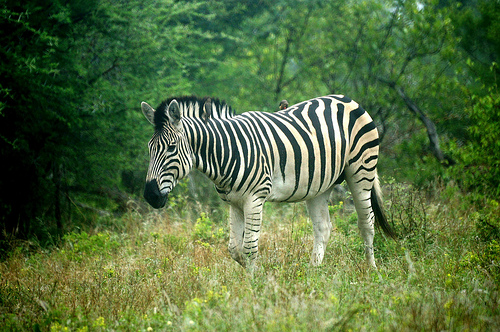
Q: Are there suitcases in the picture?
A: No, there are no suitcases.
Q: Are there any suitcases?
A: No, there are no suitcases.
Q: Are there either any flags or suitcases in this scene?
A: No, there are no suitcases or flags.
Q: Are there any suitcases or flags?
A: No, there are no suitcases or flags.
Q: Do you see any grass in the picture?
A: Yes, there is grass.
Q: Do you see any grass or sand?
A: Yes, there is grass.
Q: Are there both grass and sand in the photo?
A: No, there is grass but no sand.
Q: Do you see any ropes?
A: No, there are no ropes.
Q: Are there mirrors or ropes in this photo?
A: No, there are no ropes or mirrors.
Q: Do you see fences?
A: No, there are no fences.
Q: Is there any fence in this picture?
A: No, there are no fences.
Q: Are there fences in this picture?
A: No, there are no fences.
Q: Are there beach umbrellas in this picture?
A: No, there are no beach umbrellas.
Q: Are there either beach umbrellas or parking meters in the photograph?
A: No, there are no beach umbrellas or parking meters.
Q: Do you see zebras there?
A: Yes, there is a zebra.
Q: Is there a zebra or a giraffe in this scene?
A: Yes, there is a zebra.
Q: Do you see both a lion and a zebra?
A: No, there is a zebra but no lions.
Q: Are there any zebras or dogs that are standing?
A: Yes, the zebra is standing.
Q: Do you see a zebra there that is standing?
A: Yes, there is a zebra that is standing.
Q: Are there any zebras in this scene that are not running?
A: Yes, there is a zebra that is standing.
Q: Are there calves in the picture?
A: No, there are no calves.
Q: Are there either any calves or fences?
A: No, there are no calves or fences.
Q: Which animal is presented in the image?
A: The animal is a zebra.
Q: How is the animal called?
A: The animal is a zebra.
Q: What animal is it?
A: The animal is a zebra.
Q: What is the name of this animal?
A: This is a zebra.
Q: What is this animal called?
A: This is a zebra.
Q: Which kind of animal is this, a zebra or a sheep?
A: This is a zebra.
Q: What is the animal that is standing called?
A: The animal is a zebra.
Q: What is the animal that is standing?
A: The animal is a zebra.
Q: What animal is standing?
A: The animal is a zebra.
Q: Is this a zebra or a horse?
A: This is a zebra.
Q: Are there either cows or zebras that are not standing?
A: No, there is a zebra but it is standing.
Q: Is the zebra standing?
A: Yes, the zebra is standing.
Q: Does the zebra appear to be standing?
A: Yes, the zebra is standing.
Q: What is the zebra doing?
A: The zebra is standing.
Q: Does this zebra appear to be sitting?
A: No, the zebra is standing.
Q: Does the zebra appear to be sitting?
A: No, the zebra is standing.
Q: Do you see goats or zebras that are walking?
A: No, there is a zebra but it is standing.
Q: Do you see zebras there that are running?
A: No, there is a zebra but it is standing.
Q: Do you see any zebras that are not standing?
A: No, there is a zebra but it is standing.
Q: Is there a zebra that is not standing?
A: No, there is a zebra but it is standing.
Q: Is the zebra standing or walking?
A: The zebra is standing.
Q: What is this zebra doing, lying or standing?
A: The zebra is standing.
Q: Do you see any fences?
A: No, there are no fences.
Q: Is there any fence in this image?
A: No, there are no fences.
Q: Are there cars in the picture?
A: No, there are no cars.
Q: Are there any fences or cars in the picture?
A: No, there are no cars or fences.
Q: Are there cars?
A: No, there are no cars.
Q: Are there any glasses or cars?
A: No, there are no cars or glasses.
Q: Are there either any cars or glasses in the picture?
A: No, there are no cars or glasses.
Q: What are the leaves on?
A: The leaves are on the tree.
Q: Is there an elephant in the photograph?
A: No, there are no elephants.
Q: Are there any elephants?
A: No, there are no elephants.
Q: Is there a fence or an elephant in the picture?
A: No, there are no elephants or fences.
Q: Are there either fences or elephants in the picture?
A: No, there are no elephants or fences.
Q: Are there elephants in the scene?
A: No, there are no elephants.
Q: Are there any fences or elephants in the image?
A: No, there are no elephants or fences.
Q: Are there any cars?
A: No, there are no cars.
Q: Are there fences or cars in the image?
A: No, there are no cars or fences.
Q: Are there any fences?
A: No, there are no fences.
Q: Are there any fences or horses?
A: No, there are no fences or horses.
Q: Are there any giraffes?
A: No, there are no giraffes.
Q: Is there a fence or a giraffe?
A: No, there are no giraffes or fences.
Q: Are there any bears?
A: No, there are no bears.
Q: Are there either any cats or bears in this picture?
A: No, there are no bears or cats.